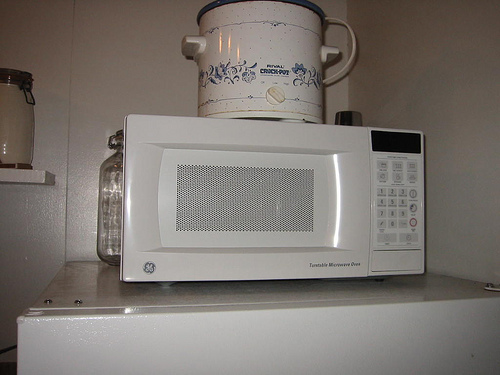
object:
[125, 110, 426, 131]
top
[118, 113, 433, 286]
microwave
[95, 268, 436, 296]
bottom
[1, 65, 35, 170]
glass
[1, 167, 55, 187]
shelf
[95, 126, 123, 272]
glass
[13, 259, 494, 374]
refrigerator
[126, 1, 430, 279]
pair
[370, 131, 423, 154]
display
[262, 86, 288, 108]
switch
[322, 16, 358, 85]
cord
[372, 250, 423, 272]
button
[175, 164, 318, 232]
window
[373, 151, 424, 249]
panel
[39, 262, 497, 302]
white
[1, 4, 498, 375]
wall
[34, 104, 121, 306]
left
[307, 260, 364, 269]
writing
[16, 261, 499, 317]
top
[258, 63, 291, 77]
logo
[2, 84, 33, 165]
white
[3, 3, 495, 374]
kitchen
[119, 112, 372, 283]
door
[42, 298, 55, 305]
screws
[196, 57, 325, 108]
design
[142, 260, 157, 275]
ge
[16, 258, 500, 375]
counter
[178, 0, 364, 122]
croc pot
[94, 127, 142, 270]
jar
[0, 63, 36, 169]
container